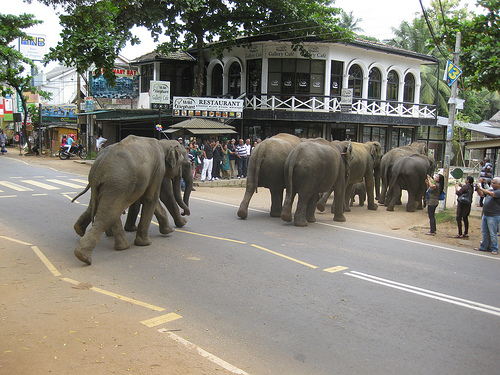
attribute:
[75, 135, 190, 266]
elephant — gray, large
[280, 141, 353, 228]
elephant — large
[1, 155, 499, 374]
street — black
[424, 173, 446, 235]
person — taking photo, taking pictures, taking picture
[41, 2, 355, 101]
tree — tall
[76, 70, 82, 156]
pole — wooden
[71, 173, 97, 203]
tail — grey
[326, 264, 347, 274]
line — yellow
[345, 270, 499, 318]
lines — double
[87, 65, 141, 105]
poster — red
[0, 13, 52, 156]
tree — green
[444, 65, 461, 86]
sign — blue